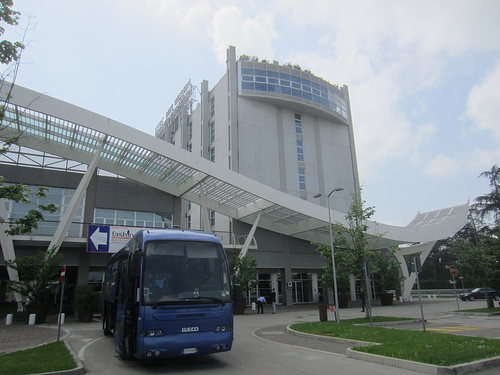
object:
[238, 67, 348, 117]
windows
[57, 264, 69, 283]
sign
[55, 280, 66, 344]
pole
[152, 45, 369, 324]
tall building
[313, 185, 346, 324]
light pole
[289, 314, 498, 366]
grass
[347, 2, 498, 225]
clouds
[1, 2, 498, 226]
sky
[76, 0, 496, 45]
sky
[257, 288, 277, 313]
people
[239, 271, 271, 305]
entryway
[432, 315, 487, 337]
street sign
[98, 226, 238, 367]
bus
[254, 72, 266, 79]
window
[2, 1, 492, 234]
cloud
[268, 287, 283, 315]
person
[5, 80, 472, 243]
railing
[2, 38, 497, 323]
building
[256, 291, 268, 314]
person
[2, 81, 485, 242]
ramp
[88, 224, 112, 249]
arrow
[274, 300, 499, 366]
island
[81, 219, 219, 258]
sign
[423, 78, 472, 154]
sky